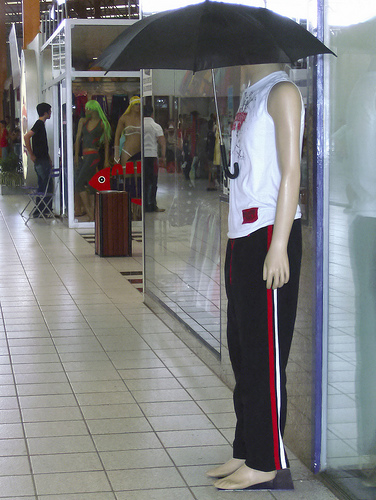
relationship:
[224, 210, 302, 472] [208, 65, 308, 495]
pants on mannequin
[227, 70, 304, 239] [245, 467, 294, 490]
shirt on display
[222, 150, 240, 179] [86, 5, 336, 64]
handle on umbrella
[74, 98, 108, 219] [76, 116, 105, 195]
mannequin wearing clothing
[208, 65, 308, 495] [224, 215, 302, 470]
mannequin wearing pants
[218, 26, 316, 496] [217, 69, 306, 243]
mannequin wearing tank top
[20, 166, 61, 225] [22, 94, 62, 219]
chair next to man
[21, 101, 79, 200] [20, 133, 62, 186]
man looking at clothes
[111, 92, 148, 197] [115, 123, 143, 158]
mannequin wearing bikini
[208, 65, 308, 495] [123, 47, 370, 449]
mannequin in window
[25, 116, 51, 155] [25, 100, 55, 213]
shirt on man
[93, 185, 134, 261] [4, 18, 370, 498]
fountain in mall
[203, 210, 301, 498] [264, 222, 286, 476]
pants with stripes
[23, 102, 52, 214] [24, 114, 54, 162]
man wearing shirt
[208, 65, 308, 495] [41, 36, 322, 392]
mannequin in window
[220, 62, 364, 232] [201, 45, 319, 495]
shirt on mannequin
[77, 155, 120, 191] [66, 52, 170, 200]
graphics on window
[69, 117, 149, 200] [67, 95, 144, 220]
clothing on mannequins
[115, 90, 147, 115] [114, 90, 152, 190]
hair on mannequin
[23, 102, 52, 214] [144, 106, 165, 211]
man has reflection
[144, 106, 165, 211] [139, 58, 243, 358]
reflection on window